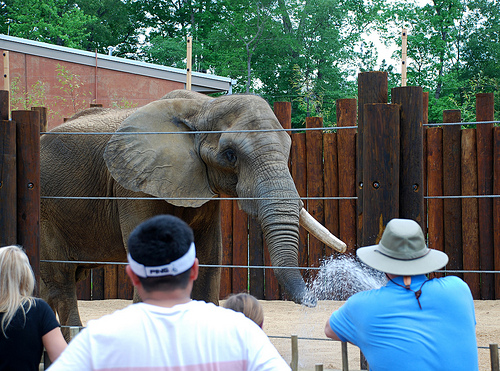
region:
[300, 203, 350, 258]
The tusk of the elephant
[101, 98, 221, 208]
The ear of the elephant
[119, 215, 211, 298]
The head of the man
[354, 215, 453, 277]
The man has on a hat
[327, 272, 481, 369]
The man has on a baby blue t shirt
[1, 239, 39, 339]
The woman has blonde hair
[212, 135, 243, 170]
The eye of the elephant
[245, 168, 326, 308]
The trunk of the elephant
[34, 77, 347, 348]
The elephant is walking forward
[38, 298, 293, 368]
The man has on a white shirt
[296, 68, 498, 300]
The fence is made of wood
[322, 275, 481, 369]
The man is wearing a baby blue shirt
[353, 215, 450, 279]
The man has on a khaki hat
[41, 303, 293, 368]
The man is wearing a white shirt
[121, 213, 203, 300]
The man has on a white head band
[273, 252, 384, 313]
The elephant is spitting out water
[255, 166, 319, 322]
The elephant trunk is gray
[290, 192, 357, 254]
an elephant's left tusk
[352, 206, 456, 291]
an olive green hat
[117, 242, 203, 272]
a white head band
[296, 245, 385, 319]
a spray of water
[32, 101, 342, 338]
an elephant in captivity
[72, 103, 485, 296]
a wood log fence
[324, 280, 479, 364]
a light blue shirt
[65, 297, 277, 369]
a white t-shirt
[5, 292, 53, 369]
a black t-shirt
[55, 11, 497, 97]
the tops of green trees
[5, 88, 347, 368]
An elephant behind a fence.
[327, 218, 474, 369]
A man spraying water on an elephant.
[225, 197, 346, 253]
The elephant has one tusk.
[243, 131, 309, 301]
Ridges on the elephants trunk.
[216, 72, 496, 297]
A brown wooden fence.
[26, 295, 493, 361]
The ground is dirt.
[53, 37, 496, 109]
Trees behind the wooden fence.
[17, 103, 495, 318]
Metal wire attached to wooden posts.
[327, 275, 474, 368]
A man wearing a blue shirt.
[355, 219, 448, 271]
A gray hat on the man's head.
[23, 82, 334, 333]
an elephant in a pen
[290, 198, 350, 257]
tusk of elephant on right side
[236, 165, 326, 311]
a trunk of elephant is long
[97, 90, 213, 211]
large ear of elephant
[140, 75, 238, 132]
a hump of elephant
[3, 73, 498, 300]
a fence of a pen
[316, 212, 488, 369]
a man wears a blue shirt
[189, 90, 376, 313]
elephant throw water with his trunk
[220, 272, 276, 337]
a blond hair of kid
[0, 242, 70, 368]
a blonde lady